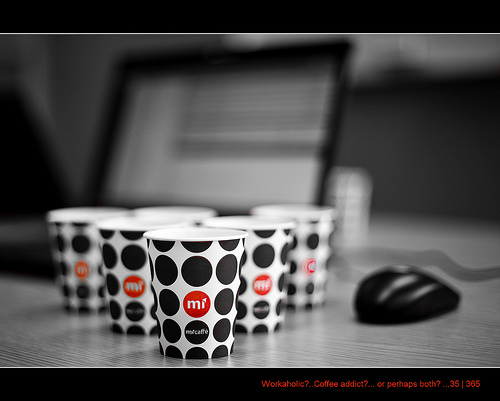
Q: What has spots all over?
A: A mug.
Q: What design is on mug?
A: Spots.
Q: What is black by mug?
A: A mouse.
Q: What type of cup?
A: Mug.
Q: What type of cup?
A: Mug.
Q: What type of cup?
A: Mug.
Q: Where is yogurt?
A: Mug.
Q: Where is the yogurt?
A: Mug.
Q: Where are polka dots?
A: Cup.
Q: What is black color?
A: Mouse.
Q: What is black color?
A: Mouse.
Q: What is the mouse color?
A: Mouse is black.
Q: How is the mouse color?
A: Mouse is black.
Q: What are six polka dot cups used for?
A: Drinking.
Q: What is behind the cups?
A: Blurred pc monitor.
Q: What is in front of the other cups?
A: Clear polka dot cup.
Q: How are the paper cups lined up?
A: Pyramid pattern.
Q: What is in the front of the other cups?
A: Paper cup.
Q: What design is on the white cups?
A: Black polka dots.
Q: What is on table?
A: Black computer mouse.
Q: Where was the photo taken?
A: On a table.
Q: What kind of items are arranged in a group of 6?
A: Cups.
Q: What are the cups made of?
A: Paper.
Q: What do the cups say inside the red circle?
A: Mi.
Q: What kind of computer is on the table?
A: A laptop.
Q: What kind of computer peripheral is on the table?
A: A mouse.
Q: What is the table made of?
A: Wood.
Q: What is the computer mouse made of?
A: Plastic.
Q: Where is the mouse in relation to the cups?
A: On the right.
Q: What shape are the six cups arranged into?
A: A triangle.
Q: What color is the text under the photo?
A: Red.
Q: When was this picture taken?
A: Daytime.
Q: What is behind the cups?
A: Laptop.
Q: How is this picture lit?
A: Indoor lighting.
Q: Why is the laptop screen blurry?
A: It's not in focus.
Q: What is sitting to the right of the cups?
A: Mouse.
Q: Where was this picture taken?
A: Table.